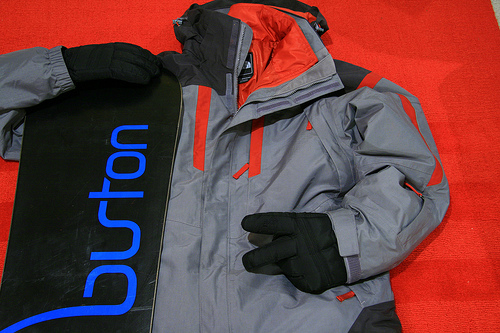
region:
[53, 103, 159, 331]
burton in blue on jacket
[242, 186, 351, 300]
black glove in jacket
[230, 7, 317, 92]
red lining in jacket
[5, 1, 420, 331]
red, gray and black jacket with large blue writing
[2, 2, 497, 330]
jacket on red cloth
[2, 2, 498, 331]
multi-colored jacket on red carpet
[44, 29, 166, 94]
black glove in jacket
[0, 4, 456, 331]
gray jacket with board on top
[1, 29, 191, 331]
blue writing on skateboard on jacket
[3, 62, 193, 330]
blue writing on skateboard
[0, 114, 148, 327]
blue logo on the snow board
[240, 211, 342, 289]
black snow glove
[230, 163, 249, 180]
red zipper pull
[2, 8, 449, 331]
multi-colored snow jacket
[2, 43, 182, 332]
black snow board with blue writing on it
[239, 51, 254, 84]
tag inside the jacket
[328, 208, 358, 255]
velcro sleeve adjuster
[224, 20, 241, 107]
velcro on the jacket neck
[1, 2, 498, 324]
jacket is on a bright red backing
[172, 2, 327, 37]
black hood on the jacket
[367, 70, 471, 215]
red stripe on jacket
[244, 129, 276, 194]
red stripe on jacket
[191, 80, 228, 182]
red strip on jacket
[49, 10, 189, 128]
black glove attached to jacket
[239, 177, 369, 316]
black glove attached to jacket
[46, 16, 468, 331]
grey and black jacket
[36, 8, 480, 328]
jacket with red stripes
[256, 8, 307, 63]
jacket with red lining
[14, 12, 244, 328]
black snowboard on jacket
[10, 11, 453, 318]
jacket and snowboard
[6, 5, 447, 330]
The jacket is on the carpet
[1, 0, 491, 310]
The carpet is red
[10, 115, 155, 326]
Blue writing on side of board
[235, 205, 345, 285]
The gloves are black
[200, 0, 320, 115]
The inside of the jacket is red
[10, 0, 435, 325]
Black and grey jacket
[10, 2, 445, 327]
The jacket is flat on the carpet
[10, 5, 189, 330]
The board is black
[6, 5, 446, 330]
The board is on top of the jacket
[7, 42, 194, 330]
The black glove is holding the board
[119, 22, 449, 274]
A gray jacket and a black snowboard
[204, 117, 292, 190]
The jacket has orange details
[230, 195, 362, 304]
A black glove for snowboarding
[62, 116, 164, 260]
A black snowboard with blue lettering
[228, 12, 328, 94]
The lining of the jacket is orange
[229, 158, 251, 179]
An orange pull for a zipper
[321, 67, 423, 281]
The sleeve of the jacket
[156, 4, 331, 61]
This is the jackets hood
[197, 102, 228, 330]
The jacket is zipped up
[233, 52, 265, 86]
The tag inside the jacket is black